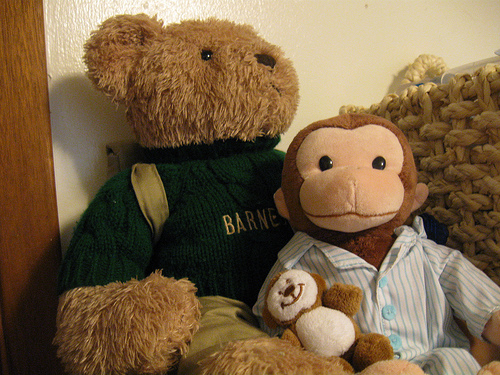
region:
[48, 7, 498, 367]
three stuffed toys gathered together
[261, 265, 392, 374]
small brown and white teddy bear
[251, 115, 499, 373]
large stuffed monkey in blue pyjamas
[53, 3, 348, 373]
large brown fuzzy teddy bear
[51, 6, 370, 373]
large teddy bear wearing green sweater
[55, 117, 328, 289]
green sweater with yellow embroidered name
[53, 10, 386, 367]
large teddy bear wearing khaki overalls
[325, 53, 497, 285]
brown wicker basket behind monkey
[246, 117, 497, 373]
stuffed brown with light brown face monkey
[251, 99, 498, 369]
monkey with small teddy bear in lap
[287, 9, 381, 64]
white part of a wall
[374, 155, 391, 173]
left eye of a doll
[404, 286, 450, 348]
stripped shirt of a doll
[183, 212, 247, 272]
a green sweater of the doll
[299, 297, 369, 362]
part of a smaller doll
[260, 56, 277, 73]
nose of a doll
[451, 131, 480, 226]
part of a chair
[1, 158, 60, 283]
part of a wooden boundary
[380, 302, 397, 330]
a button on the shirt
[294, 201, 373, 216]
mouth of the doll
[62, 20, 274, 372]
this is a teddy bear doll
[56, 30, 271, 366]
thr teddy bear doll is brown in color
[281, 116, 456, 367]
a monkey doll is beside the teddy bear doll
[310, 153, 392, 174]
the monkeys eyes are wide open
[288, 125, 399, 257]
the monkey is brown in color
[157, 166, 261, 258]
the teddy bear doll is wearing a green sweater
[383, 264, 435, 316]
the monkey doll is wearing a shirt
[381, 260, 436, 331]
the shirt is white and green in color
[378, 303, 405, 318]
the button is big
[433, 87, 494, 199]
this basket is woven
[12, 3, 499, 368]
picture of child's stuffed animals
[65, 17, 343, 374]
stuffed teddy bear wearing green sweater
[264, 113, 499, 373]
stuffed money wearing blue striped shirt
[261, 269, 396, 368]
small teddy bear being held by monkey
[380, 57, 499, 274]
woven basket beside stuffed toys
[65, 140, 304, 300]
green knit sweater on teddy bear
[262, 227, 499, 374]
blue and white shirt on stuffed monkey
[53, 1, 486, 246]
white wall behind stuffed toys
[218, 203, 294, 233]
teddy bear's name stitched on sweater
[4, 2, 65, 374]
wood moulding on wall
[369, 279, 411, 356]
blue buttons on shirt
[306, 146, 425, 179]
black eyes on a face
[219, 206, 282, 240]
logo on a sweater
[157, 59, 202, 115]
shaggy brown bear fur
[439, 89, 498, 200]
a wicker basket next to a monkey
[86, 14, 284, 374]
a stuffed bear wearing khaki pants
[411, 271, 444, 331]
blue stripes on a pajamas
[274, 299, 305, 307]
a smile on a face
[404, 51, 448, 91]
a white rope handle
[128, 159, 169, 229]
the strap on a backpack